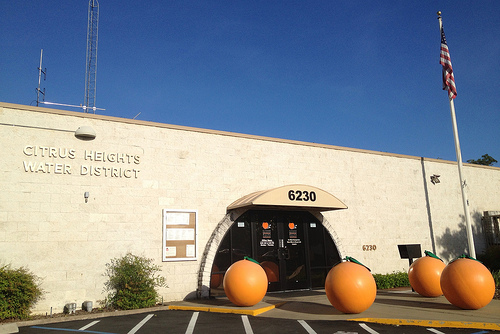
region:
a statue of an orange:
[223, 259, 270, 307]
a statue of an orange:
[328, 260, 376, 312]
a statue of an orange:
[445, 257, 490, 306]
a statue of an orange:
[406, 254, 446, 296]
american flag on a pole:
[428, 13, 497, 209]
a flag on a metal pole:
[424, 11, 481, 151]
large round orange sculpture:
[301, 245, 393, 330]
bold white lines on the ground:
[161, 313, 214, 332]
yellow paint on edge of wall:
[356, 313, 396, 324]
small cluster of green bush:
[94, 251, 166, 301]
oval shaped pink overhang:
[228, 173, 350, 217]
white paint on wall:
[28, 214, 107, 251]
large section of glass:
[240, 218, 326, 268]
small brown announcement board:
[154, 199, 203, 264]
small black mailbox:
[393, 229, 429, 264]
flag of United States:
[420, 19, 470, 111]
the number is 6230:
[275, 176, 323, 208]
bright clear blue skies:
[171, 21, 371, 96]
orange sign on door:
[256, 215, 273, 230]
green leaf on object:
[341, 246, 389, 279]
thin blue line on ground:
[37, 323, 82, 331]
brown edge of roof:
[306, 132, 437, 162]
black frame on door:
[276, 224, 293, 289]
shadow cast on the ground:
[391, 289, 443, 318]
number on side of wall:
[359, 238, 383, 250]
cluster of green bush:
[99, 250, 170, 310]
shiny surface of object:
[344, 274, 378, 292]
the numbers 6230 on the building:
[288, 187, 316, 202]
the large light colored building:
[0, 100, 496, 315]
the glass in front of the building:
[210, 206, 339, 291]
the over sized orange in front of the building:
[224, 255, 268, 305]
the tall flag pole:
[436, 10, 475, 257]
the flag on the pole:
[439, 17, 456, 99]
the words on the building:
[20, 142, 141, 178]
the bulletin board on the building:
[161, 207, 198, 262]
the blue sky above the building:
[0, 0, 499, 168]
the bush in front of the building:
[100, 250, 167, 309]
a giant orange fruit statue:
[224, 256, 267, 303]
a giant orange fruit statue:
[326, 255, 376, 312]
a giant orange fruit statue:
[441, 252, 496, 307]